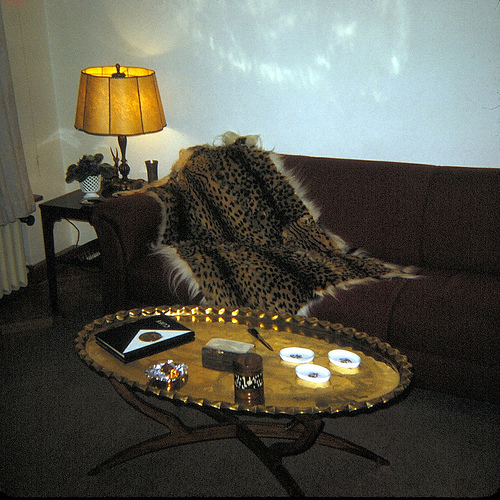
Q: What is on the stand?
A: Light.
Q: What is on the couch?
A: Fur.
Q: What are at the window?
A: Curtain.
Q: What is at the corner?
A: Stand.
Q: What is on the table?
A: Lamp.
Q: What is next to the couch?
A: A table.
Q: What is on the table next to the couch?
A: A lamp.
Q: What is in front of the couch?
A: An oval table.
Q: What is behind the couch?
A: A wall.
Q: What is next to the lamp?
A: A plant.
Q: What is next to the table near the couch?
A: A window.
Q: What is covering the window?
A: Curtains.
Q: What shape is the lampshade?
A: Circular.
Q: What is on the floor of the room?
A: Carpet.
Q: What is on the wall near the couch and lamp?
A: Glare from light.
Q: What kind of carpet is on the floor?
A: A dark carpet.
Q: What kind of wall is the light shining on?
A: A grey colored wall.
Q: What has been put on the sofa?
A: A leopard skin blanket.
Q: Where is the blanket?
A: On a brown couch.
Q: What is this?
A: Living room.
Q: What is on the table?
A: Pen.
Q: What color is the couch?
A: Brown.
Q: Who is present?
A: No one.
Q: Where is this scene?
A: In a living room.